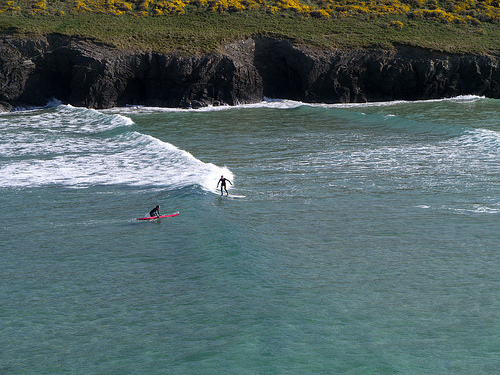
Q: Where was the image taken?
A: It was taken at the ocean.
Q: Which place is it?
A: It is an ocean.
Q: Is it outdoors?
A: Yes, it is outdoors.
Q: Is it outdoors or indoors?
A: It is outdoors.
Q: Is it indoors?
A: No, it is outdoors.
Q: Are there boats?
A: No, there are no boats.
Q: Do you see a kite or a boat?
A: No, there are no boats or kites.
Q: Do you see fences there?
A: No, there are no fences.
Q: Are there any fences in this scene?
A: No, there are no fences.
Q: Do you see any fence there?
A: No, there are no fences.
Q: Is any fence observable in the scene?
A: No, there are no fences.